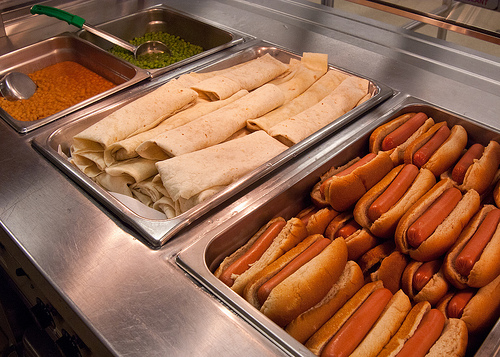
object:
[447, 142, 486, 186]
hotdogs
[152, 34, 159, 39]
peas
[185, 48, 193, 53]
peas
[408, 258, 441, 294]
hot dogs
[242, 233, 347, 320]
buns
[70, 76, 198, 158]
food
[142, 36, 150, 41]
peas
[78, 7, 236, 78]
hot tray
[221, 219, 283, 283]
hot dog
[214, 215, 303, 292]
bun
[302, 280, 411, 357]
bun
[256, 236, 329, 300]
hot dog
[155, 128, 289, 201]
burrito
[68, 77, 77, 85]
baked beans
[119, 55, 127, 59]
peas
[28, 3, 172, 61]
serving spoon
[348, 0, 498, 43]
backsplash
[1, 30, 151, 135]
tray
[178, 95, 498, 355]
tray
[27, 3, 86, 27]
handle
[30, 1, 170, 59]
untensil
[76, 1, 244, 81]
tray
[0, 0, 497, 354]
counter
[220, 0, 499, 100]
ridges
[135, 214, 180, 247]
corner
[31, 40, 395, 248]
tray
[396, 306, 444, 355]
hot dog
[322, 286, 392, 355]
hot dog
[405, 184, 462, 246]
hot dog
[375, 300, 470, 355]
bun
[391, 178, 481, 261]
bun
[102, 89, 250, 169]
burritos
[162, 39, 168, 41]
peas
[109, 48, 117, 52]
beans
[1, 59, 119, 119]
utensil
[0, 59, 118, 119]
sauce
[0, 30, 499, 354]
fast food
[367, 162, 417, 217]
hotdog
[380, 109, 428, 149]
hotdog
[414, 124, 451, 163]
hotdog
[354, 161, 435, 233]
bun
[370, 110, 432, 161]
bun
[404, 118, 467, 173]
bun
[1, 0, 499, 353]
buffet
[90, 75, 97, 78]
corn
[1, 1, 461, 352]
table